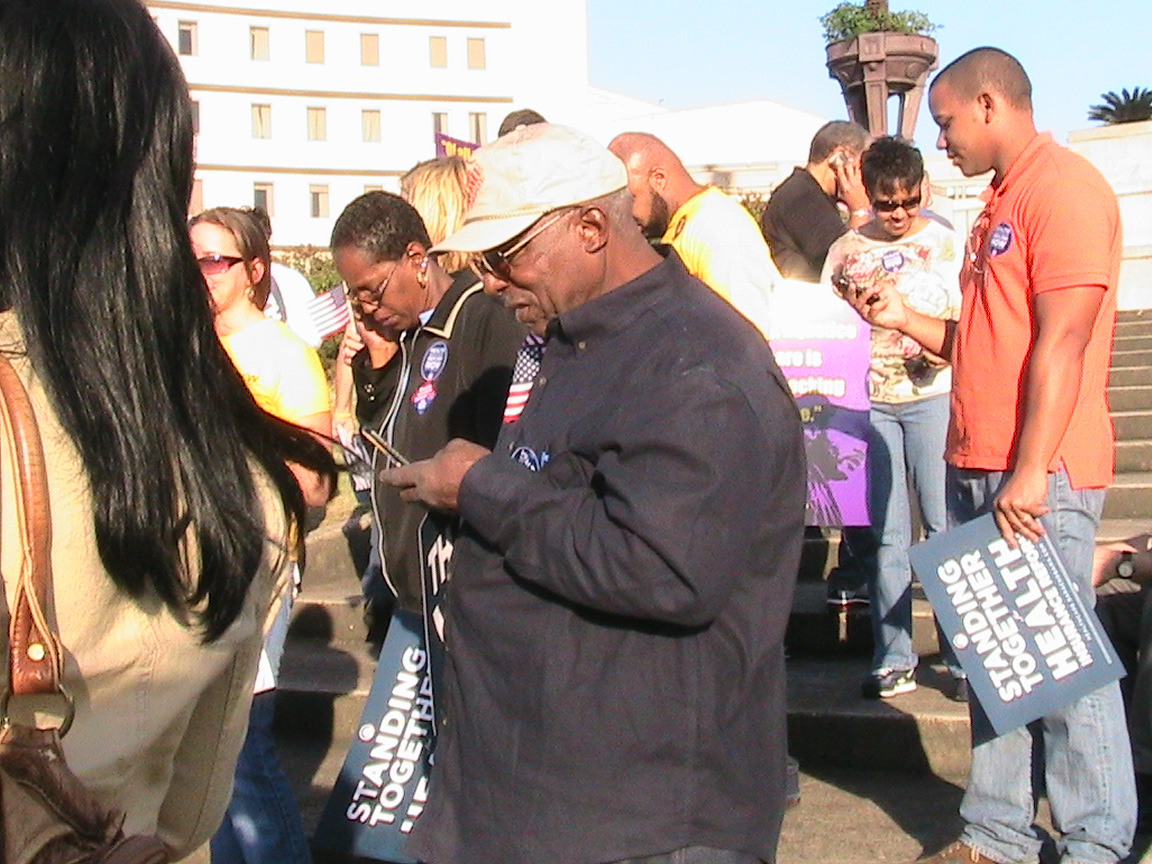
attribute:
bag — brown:
[5, 357, 185, 859]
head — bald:
[607, 119, 682, 244]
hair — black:
[2, 6, 366, 651]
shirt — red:
[943, 126, 1131, 503]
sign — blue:
[896, 492, 1128, 741]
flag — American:
[484, 339, 557, 445]